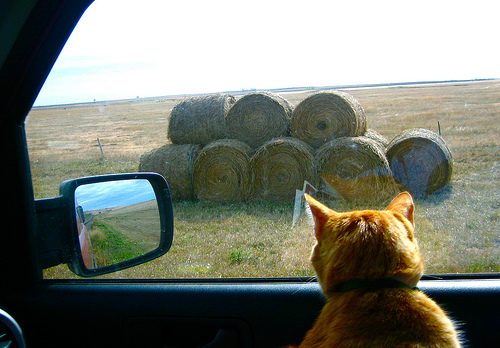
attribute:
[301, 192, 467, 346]
cat — orange, furry, golden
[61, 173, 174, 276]
mirror — black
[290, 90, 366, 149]
bale — large, rolled, round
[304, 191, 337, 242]
ear — pointy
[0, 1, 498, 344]
car — black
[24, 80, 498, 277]
field — brown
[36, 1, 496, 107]
sky — grey, cloudy